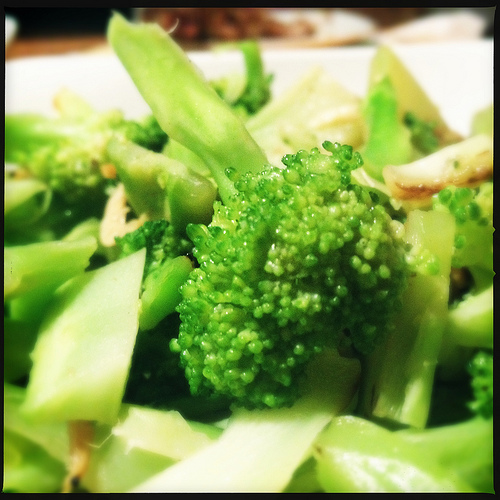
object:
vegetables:
[47, 17, 487, 440]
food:
[105, 17, 400, 389]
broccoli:
[103, 17, 271, 182]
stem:
[370, 78, 415, 174]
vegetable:
[387, 103, 495, 266]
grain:
[222, 227, 247, 247]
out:
[107, 10, 178, 57]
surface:
[55, 72, 464, 465]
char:
[403, 182, 428, 193]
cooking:
[23, 37, 500, 360]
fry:
[386, 138, 495, 211]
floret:
[233, 368, 261, 386]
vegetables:
[61, 250, 271, 408]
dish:
[7, 46, 496, 498]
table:
[2, 7, 487, 491]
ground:
[443, 212, 480, 241]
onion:
[382, 134, 497, 198]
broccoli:
[140, 253, 196, 330]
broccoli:
[213, 39, 270, 119]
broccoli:
[467, 349, 494, 419]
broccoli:
[0, 234, 97, 295]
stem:
[124, 398, 221, 462]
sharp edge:
[123, 242, 154, 325]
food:
[19, 30, 482, 487]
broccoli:
[169, 140, 422, 401]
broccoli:
[373, 222, 453, 427]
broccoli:
[111, 401, 210, 462]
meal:
[6, 10, 495, 491]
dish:
[0, 39, 493, 123]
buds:
[263, 236, 284, 273]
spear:
[28, 266, 147, 418]